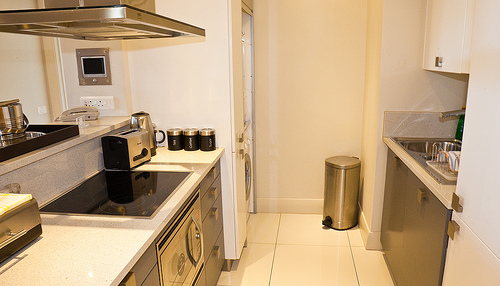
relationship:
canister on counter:
[166, 128, 183, 151] [0, 146, 225, 285]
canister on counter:
[184, 128, 199, 151] [0, 146, 225, 285]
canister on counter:
[198, 128, 217, 152] [0, 146, 225, 285]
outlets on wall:
[83, 95, 117, 110] [1, 1, 133, 117]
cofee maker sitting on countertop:
[129, 110, 166, 156] [0, 146, 225, 285]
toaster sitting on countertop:
[100, 127, 153, 171] [0, 146, 225, 285]